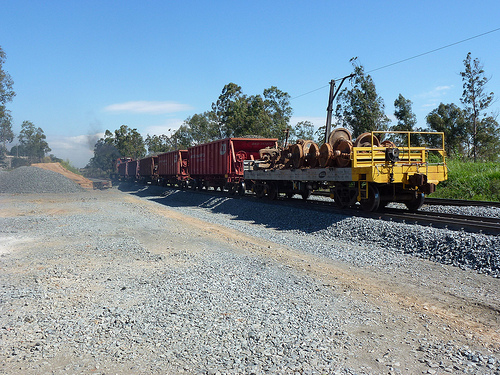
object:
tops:
[258, 84, 292, 101]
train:
[109, 126, 445, 209]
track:
[85, 176, 496, 233]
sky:
[194, 19, 266, 44]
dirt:
[236, 231, 308, 264]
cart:
[187, 133, 280, 193]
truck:
[240, 127, 451, 211]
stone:
[423, 233, 445, 246]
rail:
[423, 193, 500, 209]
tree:
[93, 128, 120, 180]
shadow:
[209, 193, 352, 235]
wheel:
[357, 183, 381, 213]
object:
[251, 146, 280, 169]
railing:
[369, 128, 446, 181]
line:
[358, 27, 500, 77]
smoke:
[88, 110, 119, 168]